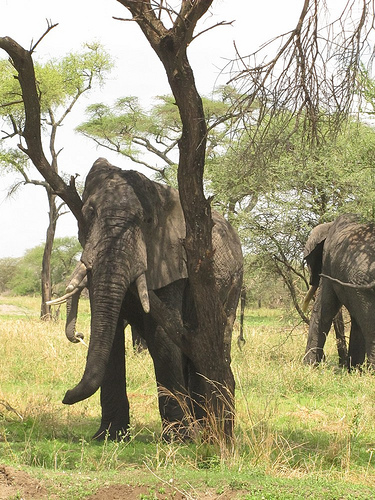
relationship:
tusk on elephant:
[65, 260, 88, 292] [45, 156, 249, 446]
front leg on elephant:
[147, 319, 196, 444] [58, 139, 251, 444]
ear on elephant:
[148, 184, 190, 290] [45, 156, 249, 446]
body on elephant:
[163, 183, 244, 328] [45, 156, 249, 446]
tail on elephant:
[315, 269, 374, 292] [299, 218, 374, 374]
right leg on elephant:
[341, 316, 366, 371] [45, 156, 249, 446]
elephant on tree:
[45, 156, 249, 446] [133, 0, 231, 439]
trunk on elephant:
[61, 262, 134, 403] [62, 161, 242, 412]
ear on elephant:
[301, 219, 335, 259] [299, 218, 374, 374]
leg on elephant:
[153, 307, 183, 438] [45, 156, 249, 446]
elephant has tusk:
[45, 156, 249, 446] [135, 264, 151, 316]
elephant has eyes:
[45, 156, 249, 446] [76, 208, 146, 233]